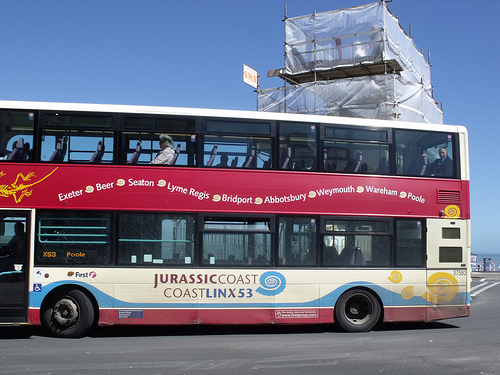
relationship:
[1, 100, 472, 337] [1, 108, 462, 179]
bus transporting passengers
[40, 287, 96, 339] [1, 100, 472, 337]
wheel on bus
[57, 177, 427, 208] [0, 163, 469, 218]
words on red portion of bus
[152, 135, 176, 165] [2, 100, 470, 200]
woman on upper level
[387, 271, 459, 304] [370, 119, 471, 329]
abstract shells on back of bus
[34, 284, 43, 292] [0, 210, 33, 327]
handicap sign near bus door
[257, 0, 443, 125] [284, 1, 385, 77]
structure wrapped in plastic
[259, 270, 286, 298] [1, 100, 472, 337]
swirl design on side of bus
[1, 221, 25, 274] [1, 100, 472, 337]
driver in his seat on bus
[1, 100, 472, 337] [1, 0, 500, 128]
bus on day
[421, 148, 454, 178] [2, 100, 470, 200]
man in top level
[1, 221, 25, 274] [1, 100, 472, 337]
driver of bus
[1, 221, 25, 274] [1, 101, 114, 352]
driver in front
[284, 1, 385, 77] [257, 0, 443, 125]
fabric covering structure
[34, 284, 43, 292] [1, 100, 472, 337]
handicap sign on bus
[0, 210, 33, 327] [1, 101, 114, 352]
door on front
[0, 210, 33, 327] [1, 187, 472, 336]
door on first level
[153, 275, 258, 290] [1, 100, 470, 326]
words on side of bus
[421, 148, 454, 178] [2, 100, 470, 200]
man on top level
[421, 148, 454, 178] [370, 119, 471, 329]
man at rear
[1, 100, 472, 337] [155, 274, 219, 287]
bus says jurassic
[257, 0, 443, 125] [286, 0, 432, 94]
scaffolding with plastic walls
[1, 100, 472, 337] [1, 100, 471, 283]
touring bus has double decks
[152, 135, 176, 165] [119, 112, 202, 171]
man in upper window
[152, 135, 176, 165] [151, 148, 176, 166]
man in white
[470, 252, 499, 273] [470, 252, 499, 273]
glimps of glimps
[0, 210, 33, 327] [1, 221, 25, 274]
door with driver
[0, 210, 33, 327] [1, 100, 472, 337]
door on bus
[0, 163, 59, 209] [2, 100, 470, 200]
animal skeleton painted on top deck of bus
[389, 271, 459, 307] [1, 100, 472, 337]
abstract shells painted on bus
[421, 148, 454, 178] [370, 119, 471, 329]
man seated in very back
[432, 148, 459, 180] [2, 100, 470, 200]
man seated in top deck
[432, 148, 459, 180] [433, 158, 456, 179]
man in black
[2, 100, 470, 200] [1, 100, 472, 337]
top section of bus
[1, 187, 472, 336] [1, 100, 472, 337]
bottom section of bus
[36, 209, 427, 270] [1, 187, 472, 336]
windows on bottom section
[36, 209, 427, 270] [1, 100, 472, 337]
windows on bus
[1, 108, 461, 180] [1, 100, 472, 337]
windows on bus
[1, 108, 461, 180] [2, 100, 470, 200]
windows on top section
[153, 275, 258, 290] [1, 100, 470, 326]
word on side of bus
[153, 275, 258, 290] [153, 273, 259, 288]
word says jurassiccoast